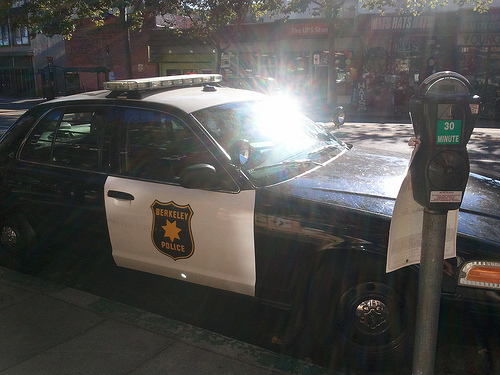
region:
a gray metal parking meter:
[404, 65, 484, 213]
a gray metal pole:
[402, 208, 453, 373]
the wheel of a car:
[303, 247, 433, 372]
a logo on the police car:
[147, 196, 202, 261]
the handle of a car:
[104, 187, 137, 206]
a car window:
[109, 98, 239, 198]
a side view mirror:
[175, 160, 227, 191]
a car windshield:
[186, 83, 341, 183]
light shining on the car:
[246, 77, 323, 140]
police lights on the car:
[95, 66, 227, 101]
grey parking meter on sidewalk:
[404, 70, 486, 370]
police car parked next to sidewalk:
[0, 61, 499, 368]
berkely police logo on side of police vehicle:
[138, 188, 204, 278]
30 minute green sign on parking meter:
[432, 115, 466, 155]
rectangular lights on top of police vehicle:
[101, 67, 230, 99]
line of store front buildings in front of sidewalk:
[3, 4, 495, 128]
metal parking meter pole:
[404, 210, 450, 374]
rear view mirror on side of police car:
[324, 100, 349, 135]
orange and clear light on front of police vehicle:
[460, 253, 499, 290]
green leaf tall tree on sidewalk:
[16, 1, 176, 81]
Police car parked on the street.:
[1, 70, 488, 361]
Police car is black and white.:
[4, 74, 495, 367]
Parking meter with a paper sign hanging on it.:
[383, 70, 483, 371]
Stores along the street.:
[5, 17, 488, 102]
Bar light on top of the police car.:
[103, 68, 228, 94]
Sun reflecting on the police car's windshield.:
[245, 76, 335, 181]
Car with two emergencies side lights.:
[225, 105, 351, 165]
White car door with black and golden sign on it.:
[105, 180, 256, 302]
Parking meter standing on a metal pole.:
[412, 210, 447, 373]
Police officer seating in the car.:
[213, 106, 243, 151]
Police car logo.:
[141, 190, 203, 271]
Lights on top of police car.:
[91, 61, 223, 93]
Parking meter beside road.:
[389, 50, 485, 372]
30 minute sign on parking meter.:
[439, 119, 462, 146]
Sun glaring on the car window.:
[251, 80, 308, 144]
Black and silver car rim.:
[337, 282, 402, 349]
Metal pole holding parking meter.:
[406, 208, 453, 365]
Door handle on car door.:
[107, 187, 134, 204]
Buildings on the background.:
[34, 33, 499, 126]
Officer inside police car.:
[214, 116, 266, 183]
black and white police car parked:
[9, 99, 491, 334]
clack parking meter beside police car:
[399, 71, 473, 371]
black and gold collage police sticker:
[150, 197, 195, 261]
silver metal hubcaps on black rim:
[349, 289, 398, 344]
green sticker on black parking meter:
[434, 119, 462, 151]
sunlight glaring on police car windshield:
[245, 82, 314, 141]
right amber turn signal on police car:
[465, 264, 495, 284]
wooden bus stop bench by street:
[51, 65, 112, 93]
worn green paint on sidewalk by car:
[94, 297, 161, 329]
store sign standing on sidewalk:
[356, 75, 371, 117]